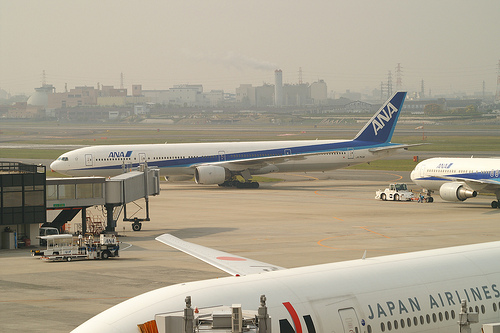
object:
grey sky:
[165, 51, 223, 72]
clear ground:
[229, 186, 395, 252]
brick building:
[173, 83, 200, 106]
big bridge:
[320, 100, 379, 113]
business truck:
[33, 229, 121, 261]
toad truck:
[374, 183, 416, 202]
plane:
[410, 157, 500, 209]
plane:
[46, 91, 434, 191]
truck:
[26, 223, 59, 247]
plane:
[66, 232, 499, 332]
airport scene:
[0, 91, 500, 330]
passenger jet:
[48, 91, 429, 191]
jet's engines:
[192, 165, 227, 185]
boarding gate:
[48, 165, 161, 207]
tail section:
[349, 90, 429, 158]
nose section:
[45, 149, 80, 178]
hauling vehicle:
[38, 229, 122, 259]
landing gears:
[237, 181, 260, 188]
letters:
[363, 304, 375, 320]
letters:
[428, 294, 439, 310]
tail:
[353, 89, 408, 142]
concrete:
[354, 207, 455, 248]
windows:
[419, 316, 425, 326]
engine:
[439, 180, 477, 204]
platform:
[0, 178, 499, 247]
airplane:
[63, 235, 496, 333]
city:
[26, 71, 334, 119]